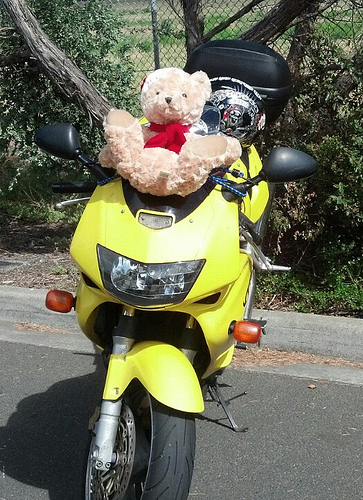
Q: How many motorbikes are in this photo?
A: One.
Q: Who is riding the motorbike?
A: No one.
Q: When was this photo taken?
A: Daytime.